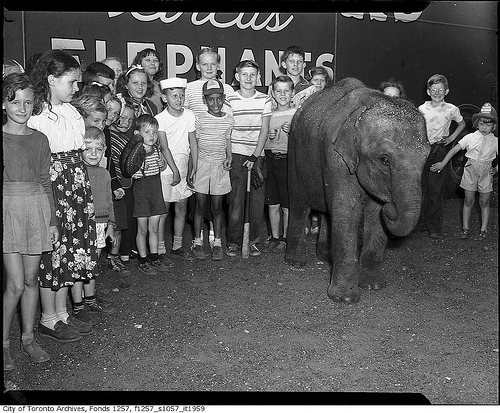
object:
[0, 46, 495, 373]
children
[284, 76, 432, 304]
elephant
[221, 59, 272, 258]
boy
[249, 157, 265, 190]
mitt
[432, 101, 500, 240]
girl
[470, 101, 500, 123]
hat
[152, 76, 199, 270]
boy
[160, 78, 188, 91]
sailor hat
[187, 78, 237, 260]
boy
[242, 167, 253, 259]
bat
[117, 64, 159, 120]
girl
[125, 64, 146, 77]
headband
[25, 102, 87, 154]
shirt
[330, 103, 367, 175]
ear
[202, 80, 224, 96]
cap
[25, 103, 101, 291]
dress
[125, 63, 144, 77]
bow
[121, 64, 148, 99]
head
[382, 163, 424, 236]
trunk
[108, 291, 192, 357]
snow